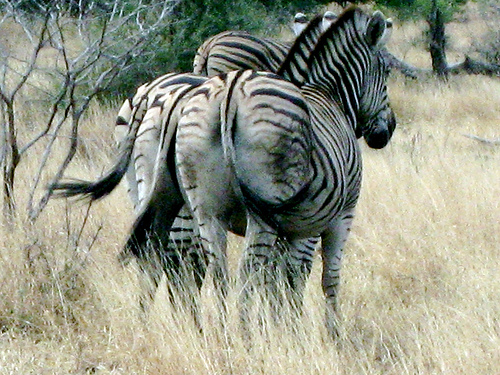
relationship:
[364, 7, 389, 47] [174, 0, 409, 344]
ear of zebra